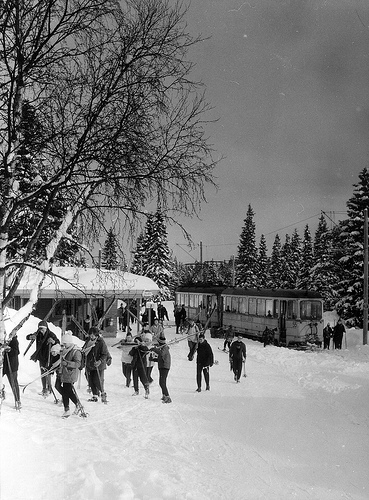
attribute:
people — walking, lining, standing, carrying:
[3, 301, 254, 412]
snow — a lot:
[2, 299, 366, 489]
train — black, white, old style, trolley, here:
[172, 284, 325, 345]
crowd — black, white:
[1, 287, 353, 410]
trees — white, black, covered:
[6, 3, 238, 393]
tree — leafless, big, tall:
[6, 4, 227, 378]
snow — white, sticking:
[3, 162, 100, 411]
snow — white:
[95, 165, 368, 332]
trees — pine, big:
[86, 167, 365, 303]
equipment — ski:
[18, 299, 199, 409]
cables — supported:
[173, 201, 361, 250]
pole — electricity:
[195, 240, 207, 283]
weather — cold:
[5, 3, 366, 492]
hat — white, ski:
[62, 327, 74, 345]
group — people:
[1, 310, 254, 411]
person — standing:
[330, 319, 348, 356]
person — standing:
[321, 321, 335, 350]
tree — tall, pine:
[234, 199, 259, 287]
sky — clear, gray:
[18, 5, 368, 269]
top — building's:
[4, 257, 163, 302]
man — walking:
[186, 332, 213, 392]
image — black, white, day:
[5, 0, 367, 492]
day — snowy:
[1, 6, 364, 496]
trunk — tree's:
[3, 175, 96, 393]